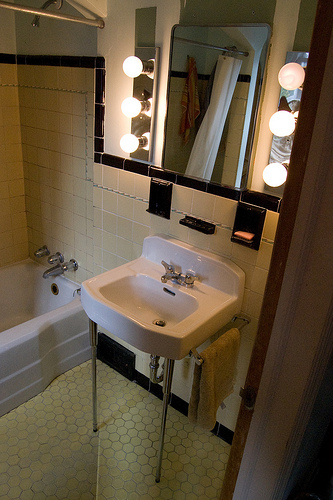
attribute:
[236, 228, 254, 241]
soap — pink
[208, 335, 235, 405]
towel — hanging, brown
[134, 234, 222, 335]
sink — white, porcelain, stand-alone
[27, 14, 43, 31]
head — metal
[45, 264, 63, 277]
faucet — steel, silver-colored, silver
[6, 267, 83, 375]
bathtub — off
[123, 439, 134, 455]
tiles — hexagonal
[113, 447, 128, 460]
tile — yellow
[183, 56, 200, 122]
towel — hanging, yellow, orange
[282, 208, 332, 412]
door — open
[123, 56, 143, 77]
lights — on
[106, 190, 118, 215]
tiles — yellow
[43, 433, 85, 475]
floor — yellowish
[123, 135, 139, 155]
knob — white